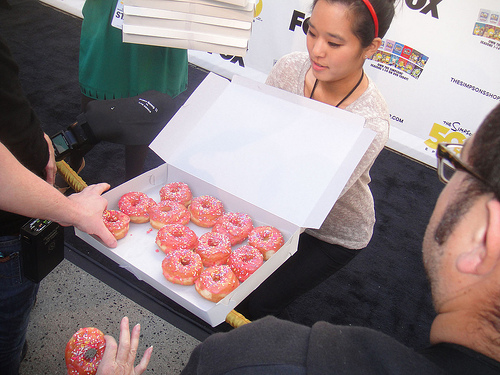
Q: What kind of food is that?
A: Donuts.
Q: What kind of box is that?
A: A large white box.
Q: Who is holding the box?
A: A woman in a white shirt.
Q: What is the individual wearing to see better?
A: Glasses.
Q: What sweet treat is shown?
A: Doughnuts.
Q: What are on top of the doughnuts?
A: Sprinkles.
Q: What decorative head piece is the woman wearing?
A: A head band.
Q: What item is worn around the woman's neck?
A: A necklace.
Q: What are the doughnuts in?
A: A box.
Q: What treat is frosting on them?
A: Doughnuts.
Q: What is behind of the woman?
A: A advertisement.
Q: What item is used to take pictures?
A: A camera.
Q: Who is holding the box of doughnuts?
A: A woman.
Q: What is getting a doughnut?
A: A hand.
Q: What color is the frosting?
A: Pink.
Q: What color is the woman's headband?
A: Red.